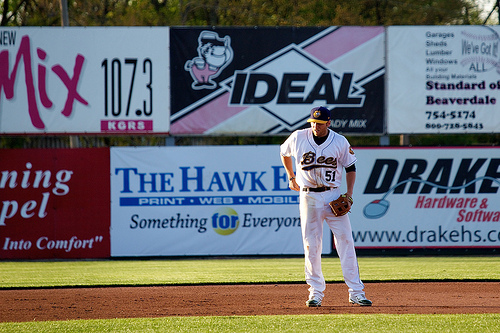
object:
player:
[278, 106, 375, 309]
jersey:
[276, 124, 361, 191]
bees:
[300, 150, 339, 165]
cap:
[303, 108, 336, 123]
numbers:
[98, 57, 158, 119]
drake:
[364, 157, 500, 195]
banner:
[354, 151, 498, 252]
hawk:
[113, 163, 268, 195]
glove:
[325, 193, 359, 218]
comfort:
[38, 237, 97, 249]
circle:
[210, 210, 237, 238]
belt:
[303, 186, 336, 193]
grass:
[0, 256, 500, 285]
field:
[0, 259, 499, 333]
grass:
[0, 315, 499, 332]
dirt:
[5, 285, 296, 313]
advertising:
[0, 25, 499, 261]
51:
[322, 167, 334, 183]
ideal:
[230, 72, 366, 108]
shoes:
[347, 289, 377, 308]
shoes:
[304, 292, 320, 310]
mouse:
[360, 193, 390, 220]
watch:
[289, 177, 295, 182]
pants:
[294, 191, 367, 301]